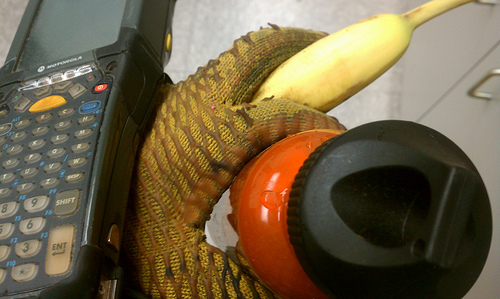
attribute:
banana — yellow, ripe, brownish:
[241, 0, 479, 116]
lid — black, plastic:
[287, 119, 493, 297]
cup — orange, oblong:
[209, 127, 347, 298]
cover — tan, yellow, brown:
[120, 22, 349, 298]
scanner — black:
[0, 2, 175, 299]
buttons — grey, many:
[2, 68, 108, 284]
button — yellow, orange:
[27, 94, 66, 113]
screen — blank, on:
[18, 0, 125, 56]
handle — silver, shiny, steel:
[466, 66, 499, 104]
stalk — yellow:
[403, 1, 475, 34]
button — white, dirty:
[43, 224, 74, 277]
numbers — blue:
[43, 208, 55, 218]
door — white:
[414, 44, 499, 298]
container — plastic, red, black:
[204, 120, 495, 298]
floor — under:
[1, 3, 402, 129]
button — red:
[92, 82, 109, 92]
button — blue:
[82, 100, 99, 111]